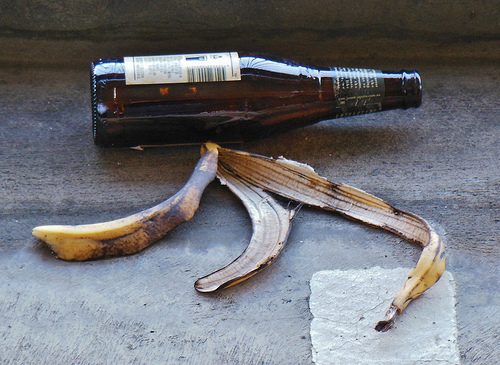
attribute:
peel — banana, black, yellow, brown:
[32, 139, 447, 332]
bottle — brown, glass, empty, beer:
[90, 51, 423, 145]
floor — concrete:
[1, 1, 499, 365]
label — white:
[124, 52, 243, 86]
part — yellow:
[32, 216, 141, 239]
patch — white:
[308, 265, 461, 364]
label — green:
[330, 65, 387, 118]